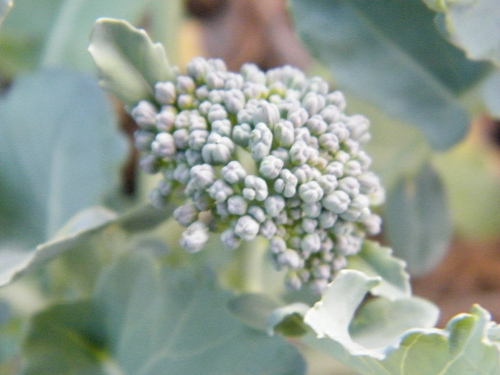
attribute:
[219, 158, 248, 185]
bud — closed, in bunch, at tip of plant, blooming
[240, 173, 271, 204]
bud — closed, in bunch, at tip of plant, blooming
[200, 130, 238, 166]
bud — closed, in bunch, at tip of plant, blooming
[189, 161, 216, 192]
bud — closed, in bunch, at tip of plant, blooming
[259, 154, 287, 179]
bud — closed, in bunch, at tip of plant, blooming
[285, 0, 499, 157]
leaf — green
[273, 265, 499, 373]
leaf — green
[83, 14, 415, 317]
plant — green, light green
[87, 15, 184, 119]
leaf — green, veined, small, white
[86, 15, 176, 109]
leaves — curved, succulent, big, small, green, irregular, red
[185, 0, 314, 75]
plant — brown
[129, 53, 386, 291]
vegetable — green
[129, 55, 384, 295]
broccoli — growing, edible, green, small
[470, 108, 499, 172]
flowers — purple, white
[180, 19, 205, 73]
dress — yellow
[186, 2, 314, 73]
background — brown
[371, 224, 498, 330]
ground — brown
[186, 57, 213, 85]
bud — white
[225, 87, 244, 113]
bud — white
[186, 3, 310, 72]
area — brown